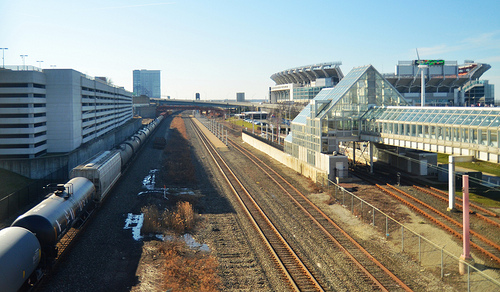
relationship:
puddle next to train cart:
[124, 210, 144, 241] [10, 173, 95, 286]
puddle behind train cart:
[124, 210, 144, 241] [10, 173, 95, 286]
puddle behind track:
[124, 210, 144, 241] [184, 109, 334, 292]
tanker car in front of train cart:
[2, 227, 41, 291] [10, 176, 95, 268]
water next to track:
[158, 234, 214, 254] [184, 109, 334, 292]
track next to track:
[184, 109, 334, 292] [203, 109, 418, 291]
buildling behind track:
[131, 69, 162, 102] [184, 109, 334, 292]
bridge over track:
[151, 96, 262, 118] [184, 109, 334, 292]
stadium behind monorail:
[269, 58, 496, 107] [361, 104, 499, 215]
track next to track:
[203, 109, 418, 291] [184, 109, 334, 292]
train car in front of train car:
[113, 142, 134, 173] [125, 136, 142, 156]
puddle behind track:
[152, 231, 211, 257] [184, 109, 334, 292]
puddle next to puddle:
[152, 231, 211, 257] [124, 210, 144, 241]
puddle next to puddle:
[124, 210, 144, 241] [152, 231, 211, 257]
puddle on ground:
[124, 210, 144, 241] [0, 105, 499, 291]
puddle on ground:
[152, 231, 211, 257] [0, 105, 499, 291]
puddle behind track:
[178, 184, 195, 193] [184, 109, 334, 292]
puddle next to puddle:
[178, 184, 195, 193] [177, 191, 198, 195]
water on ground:
[158, 234, 214, 254] [0, 105, 499, 291]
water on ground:
[135, 191, 163, 198] [0, 105, 499, 291]